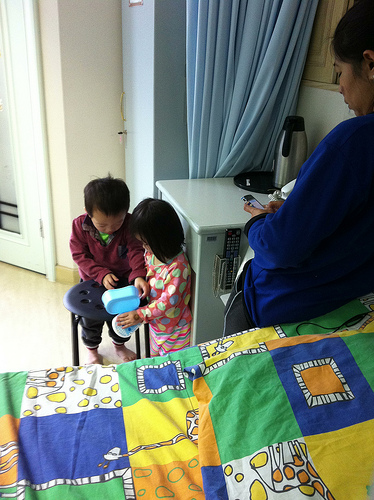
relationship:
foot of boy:
[76, 338, 137, 374] [62, 167, 160, 302]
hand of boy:
[108, 302, 147, 327] [62, 167, 160, 302]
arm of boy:
[87, 229, 128, 284] [62, 167, 160, 302]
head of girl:
[134, 198, 239, 279] [122, 194, 213, 402]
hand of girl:
[108, 302, 147, 327] [122, 194, 213, 402]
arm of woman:
[248, 173, 335, 275] [276, 28, 359, 299]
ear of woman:
[358, 31, 373, 78] [276, 28, 359, 299]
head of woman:
[327, 27, 374, 118] [276, 28, 359, 299]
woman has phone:
[276, 28, 359, 299] [228, 177, 301, 267]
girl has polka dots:
[122, 194, 213, 402] [149, 260, 215, 329]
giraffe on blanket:
[247, 426, 326, 491] [127, 410, 137, 413]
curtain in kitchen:
[179, 26, 286, 129] [40, 67, 373, 403]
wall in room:
[55, 43, 113, 112] [47, 31, 310, 475]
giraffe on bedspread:
[247, 426, 326, 491] [193, 348, 347, 498]